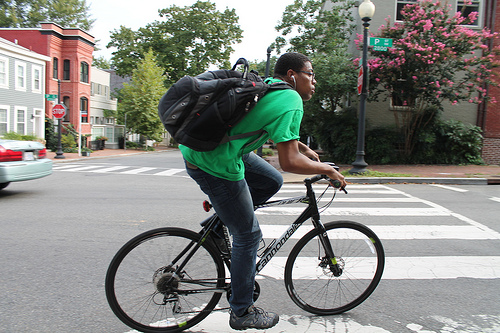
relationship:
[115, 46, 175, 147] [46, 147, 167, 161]
tree along curb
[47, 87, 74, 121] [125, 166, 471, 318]
stop sign on left side of road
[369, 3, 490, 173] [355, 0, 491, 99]
tree with blooms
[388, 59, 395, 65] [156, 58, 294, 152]
blooms wearing backpack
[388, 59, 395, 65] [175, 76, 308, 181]
blooms wearing green shirt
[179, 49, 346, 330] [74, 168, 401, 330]
boy riding bike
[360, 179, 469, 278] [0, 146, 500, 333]
lines in road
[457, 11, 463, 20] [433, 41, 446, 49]
flower on tree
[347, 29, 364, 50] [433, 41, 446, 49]
flower on tree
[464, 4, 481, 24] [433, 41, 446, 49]
flower on tree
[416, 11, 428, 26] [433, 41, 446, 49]
flower on tree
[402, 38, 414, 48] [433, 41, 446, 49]
flower on tree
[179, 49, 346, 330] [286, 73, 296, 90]
boy wearing earplugs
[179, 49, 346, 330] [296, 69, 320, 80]
boy wearing glasses